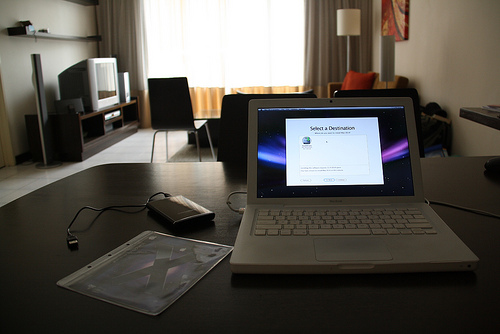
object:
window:
[143, 0, 304, 88]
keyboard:
[254, 207, 438, 236]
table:
[188, 109, 221, 147]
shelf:
[8, 27, 103, 43]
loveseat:
[327, 69, 410, 98]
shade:
[364, 33, 372, 53]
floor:
[0, 119, 218, 208]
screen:
[255, 106, 415, 198]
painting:
[380, 0, 409, 41]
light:
[153, 13, 289, 77]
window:
[284, 117, 383, 187]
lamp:
[336, 8, 361, 36]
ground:
[105, 143, 160, 162]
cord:
[67, 191, 170, 244]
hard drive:
[146, 194, 215, 227]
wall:
[0, 0, 499, 170]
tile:
[1, 178, 37, 190]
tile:
[114, 140, 133, 154]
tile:
[8, 165, 44, 178]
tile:
[3, 164, 23, 169]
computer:
[228, 97, 480, 273]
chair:
[147, 77, 216, 162]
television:
[58, 57, 121, 113]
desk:
[0, 154, 499, 334]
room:
[0, 0, 500, 333]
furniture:
[214, 70, 410, 162]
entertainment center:
[46, 58, 141, 163]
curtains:
[95, 0, 372, 129]